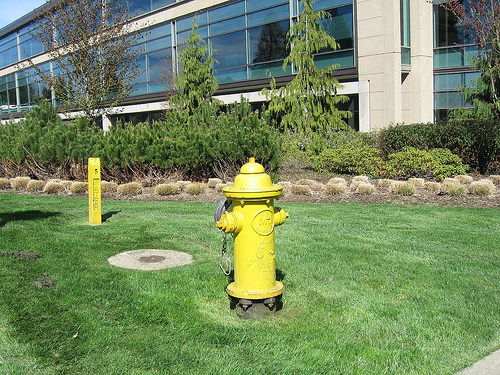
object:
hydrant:
[214, 157, 289, 319]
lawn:
[1, 195, 500, 375]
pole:
[87, 157, 103, 225]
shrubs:
[2, 97, 279, 183]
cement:
[107, 248, 193, 271]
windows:
[172, 3, 355, 95]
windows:
[47, 19, 177, 108]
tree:
[8, 1, 159, 138]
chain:
[218, 230, 233, 275]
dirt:
[276, 170, 361, 186]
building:
[0, 0, 500, 139]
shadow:
[0, 208, 62, 228]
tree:
[256, 2, 359, 136]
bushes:
[382, 147, 466, 180]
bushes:
[312, 144, 385, 174]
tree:
[162, 11, 222, 133]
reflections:
[245, 14, 289, 71]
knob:
[237, 157, 267, 174]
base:
[235, 298, 277, 319]